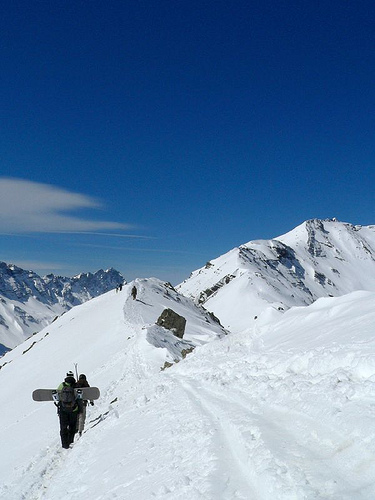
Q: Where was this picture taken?
A: On a mountain.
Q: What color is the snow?
A: White.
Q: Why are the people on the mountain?
A: To snowboard.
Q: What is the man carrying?
A: A snowboard.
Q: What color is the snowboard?
A: Black.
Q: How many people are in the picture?
A: Two.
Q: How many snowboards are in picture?
A: One.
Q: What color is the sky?
A: Blue.